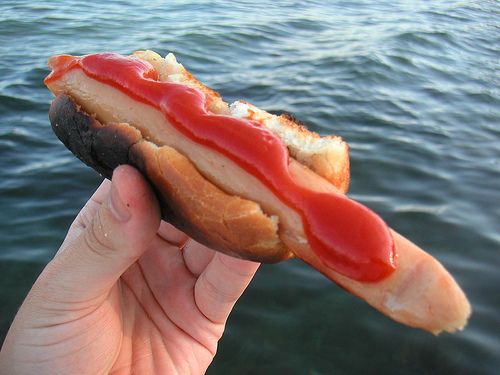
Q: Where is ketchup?
A: On hot dog.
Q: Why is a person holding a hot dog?
A: To eat it.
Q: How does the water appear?
A: Calm.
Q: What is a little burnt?
A: Hot dog bun.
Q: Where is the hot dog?
A: In person's hand.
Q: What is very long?
A: Hot dog.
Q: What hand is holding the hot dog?
A: Left hand.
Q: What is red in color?
A: Ketchup.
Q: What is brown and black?
A: Hot dog bun.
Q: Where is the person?
A: Near the water.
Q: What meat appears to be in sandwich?
A: Hot dog.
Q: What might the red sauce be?
A: Ketchup.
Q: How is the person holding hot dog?
A: In hand.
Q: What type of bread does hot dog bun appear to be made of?
A: White.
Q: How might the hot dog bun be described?
A: Brown and white with burned spot.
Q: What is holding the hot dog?
A: A hand.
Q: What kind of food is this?
A: Hot dog.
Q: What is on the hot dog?
A: Ketchup.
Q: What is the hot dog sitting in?
A: Hot dog bun.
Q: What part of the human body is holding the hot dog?
A: Hand.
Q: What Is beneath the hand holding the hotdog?
A: Body of water.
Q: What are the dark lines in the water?
A: Ripples.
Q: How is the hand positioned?
A: Bent.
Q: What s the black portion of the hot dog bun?
A: Burn marks.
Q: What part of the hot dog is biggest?
A: Hot dog.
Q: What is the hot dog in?
A: A bun.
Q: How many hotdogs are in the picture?
A: One.